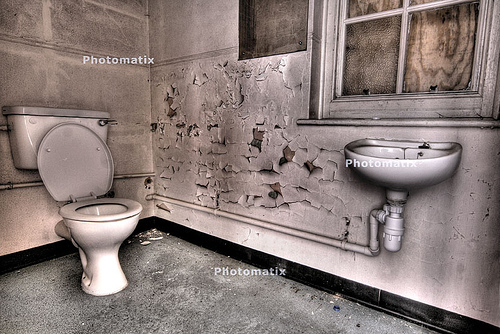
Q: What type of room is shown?
A: It is a bathroom.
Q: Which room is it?
A: It is a bathroom.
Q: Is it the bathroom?
A: Yes, it is the bathroom.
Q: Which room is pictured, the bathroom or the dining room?
A: It is the bathroom.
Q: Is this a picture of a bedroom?
A: No, the picture is showing a bathroom.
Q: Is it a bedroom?
A: No, it is a bathroom.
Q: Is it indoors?
A: Yes, it is indoors.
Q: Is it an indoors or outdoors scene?
A: It is indoors.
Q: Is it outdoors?
A: No, it is indoors.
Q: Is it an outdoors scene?
A: No, it is indoors.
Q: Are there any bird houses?
A: No, there are no bird houses.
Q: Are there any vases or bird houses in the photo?
A: No, there are no bird houses or vases.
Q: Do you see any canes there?
A: No, there are no canes.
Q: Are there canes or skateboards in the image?
A: No, there are no canes or skateboards.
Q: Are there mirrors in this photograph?
A: Yes, there is a mirror.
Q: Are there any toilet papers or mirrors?
A: Yes, there is a mirror.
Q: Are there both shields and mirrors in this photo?
A: No, there is a mirror but no shields.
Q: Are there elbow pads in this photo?
A: No, there are no elbow pads.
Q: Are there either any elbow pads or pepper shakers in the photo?
A: No, there are no elbow pads or pepper shakers.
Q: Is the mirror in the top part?
A: Yes, the mirror is in the top of the image.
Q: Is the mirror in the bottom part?
A: No, the mirror is in the top of the image.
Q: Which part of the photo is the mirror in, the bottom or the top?
A: The mirror is in the top of the image.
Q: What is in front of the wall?
A: The mirror is in front of the wall.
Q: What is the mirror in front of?
A: The mirror is in front of the wall.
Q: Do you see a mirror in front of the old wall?
A: Yes, there is a mirror in front of the wall.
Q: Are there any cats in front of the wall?
A: No, there is a mirror in front of the wall.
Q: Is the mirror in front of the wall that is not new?
A: Yes, the mirror is in front of the wall.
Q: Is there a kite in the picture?
A: No, there are no kites.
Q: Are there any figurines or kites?
A: No, there are no kites or figurines.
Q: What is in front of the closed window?
A: The sink is in front of the window.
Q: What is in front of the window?
A: The sink is in front of the window.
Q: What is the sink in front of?
A: The sink is in front of the window.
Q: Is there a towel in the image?
A: No, there are no towels.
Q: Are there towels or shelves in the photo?
A: No, there are no towels or shelves.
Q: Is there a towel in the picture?
A: No, there are no towels.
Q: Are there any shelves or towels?
A: No, there are no towels or shelves.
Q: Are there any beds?
A: No, there are no beds.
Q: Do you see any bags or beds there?
A: No, there are no beds or bags.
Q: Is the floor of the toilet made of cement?
A: Yes, the floor is made of cement.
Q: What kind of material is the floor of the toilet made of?
A: The floor is made of cement.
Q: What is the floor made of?
A: The floor is made of concrete.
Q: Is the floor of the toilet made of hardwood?
A: No, the floor is made of cement.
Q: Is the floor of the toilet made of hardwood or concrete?
A: The floor is made of concrete.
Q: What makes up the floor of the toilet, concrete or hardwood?
A: The floor is made of concrete.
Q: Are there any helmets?
A: No, there are no helmets.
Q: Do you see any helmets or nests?
A: No, there are no helmets or nests.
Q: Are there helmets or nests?
A: No, there are no helmets or nests.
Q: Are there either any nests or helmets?
A: No, there are no helmets or nests.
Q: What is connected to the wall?
A: The pipe is connected to the wall.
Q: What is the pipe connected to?
A: The pipe is connected to the wall.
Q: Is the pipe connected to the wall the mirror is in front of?
A: Yes, the pipe is connected to the wall.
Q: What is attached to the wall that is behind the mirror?
A: The pipe is attached to the wall.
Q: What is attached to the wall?
A: The pipe is attached to the wall.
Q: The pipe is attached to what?
A: The pipe is attached to the wall.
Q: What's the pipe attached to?
A: The pipe is attached to the wall.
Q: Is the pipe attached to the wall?
A: Yes, the pipe is attached to the wall.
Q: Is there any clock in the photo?
A: No, there are no clocks.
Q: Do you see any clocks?
A: No, there are no clocks.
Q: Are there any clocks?
A: No, there are no clocks.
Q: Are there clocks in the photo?
A: No, there are no clocks.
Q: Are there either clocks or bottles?
A: No, there are no clocks or bottles.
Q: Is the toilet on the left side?
A: Yes, the toilet is on the left of the image.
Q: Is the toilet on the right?
A: No, the toilet is on the left of the image.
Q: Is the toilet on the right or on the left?
A: The toilet is on the left of the image.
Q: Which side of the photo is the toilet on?
A: The toilet is on the left of the image.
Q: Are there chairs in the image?
A: No, there are no chairs.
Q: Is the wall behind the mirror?
A: Yes, the wall is behind the mirror.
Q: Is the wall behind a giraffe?
A: No, the wall is behind the mirror.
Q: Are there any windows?
A: Yes, there is a window.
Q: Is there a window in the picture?
A: Yes, there is a window.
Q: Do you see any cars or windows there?
A: Yes, there is a window.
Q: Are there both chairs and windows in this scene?
A: No, there is a window but no chairs.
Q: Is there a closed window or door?
A: Yes, there is a closed window.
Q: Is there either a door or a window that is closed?
A: Yes, the window is closed.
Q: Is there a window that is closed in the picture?
A: Yes, there is a closed window.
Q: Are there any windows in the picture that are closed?
A: Yes, there is a window that is closed.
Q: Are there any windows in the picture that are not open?
A: Yes, there is an closed window.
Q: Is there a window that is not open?
A: Yes, there is an closed window.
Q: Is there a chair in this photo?
A: No, there are no chairs.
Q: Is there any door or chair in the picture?
A: No, there are no chairs or doors.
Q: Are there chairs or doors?
A: No, there are no chairs or doors.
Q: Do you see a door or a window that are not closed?
A: No, there is a window but it is closed.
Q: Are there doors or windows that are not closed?
A: No, there is a window but it is closed.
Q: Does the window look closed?
A: Yes, the window is closed.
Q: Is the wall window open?
A: No, the window is closed.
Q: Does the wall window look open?
A: No, the window is closed.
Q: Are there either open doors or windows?
A: No, there is a window but it is closed.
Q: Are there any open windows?
A: No, there is a window but it is closed.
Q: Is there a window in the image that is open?
A: No, there is a window but it is closed.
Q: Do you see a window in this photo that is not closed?
A: No, there is a window but it is closed.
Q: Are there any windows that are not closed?
A: No, there is a window but it is closed.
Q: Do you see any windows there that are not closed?
A: No, there is a window but it is closed.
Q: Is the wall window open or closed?
A: The window is closed.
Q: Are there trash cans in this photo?
A: No, there are no trash cans.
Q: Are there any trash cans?
A: No, there are no trash cans.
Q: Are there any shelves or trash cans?
A: No, there are no trash cans or shelves.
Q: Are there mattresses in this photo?
A: No, there are no mattresses.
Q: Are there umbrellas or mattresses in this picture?
A: No, there are no mattresses or umbrellas.